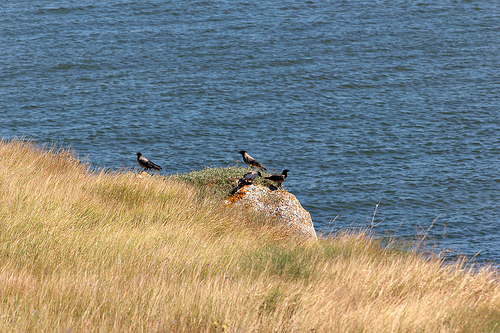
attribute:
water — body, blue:
[2, 1, 498, 271]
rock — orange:
[164, 162, 322, 245]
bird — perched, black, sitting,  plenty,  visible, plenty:
[238, 149, 266, 172]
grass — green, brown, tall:
[0, 134, 499, 332]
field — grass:
[1, 143, 499, 332]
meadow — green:
[2, 140, 499, 333]